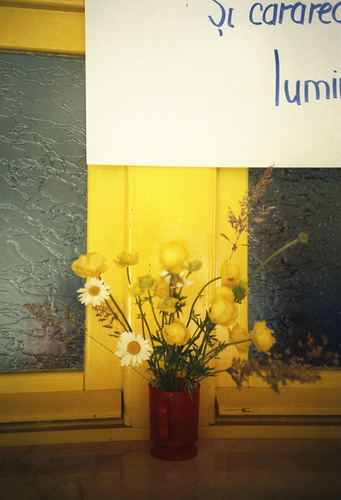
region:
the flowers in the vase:
[70, 165, 335, 391]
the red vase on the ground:
[148, 375, 197, 464]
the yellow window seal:
[0, 382, 120, 426]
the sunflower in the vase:
[111, 324, 150, 364]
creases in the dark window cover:
[0, 54, 82, 358]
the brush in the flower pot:
[213, 154, 274, 249]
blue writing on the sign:
[199, 1, 335, 128]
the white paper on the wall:
[79, 0, 336, 168]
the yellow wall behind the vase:
[83, 162, 246, 229]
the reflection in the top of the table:
[10, 443, 137, 499]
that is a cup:
[144, 383, 199, 450]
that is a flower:
[116, 329, 160, 390]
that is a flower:
[160, 320, 193, 361]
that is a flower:
[247, 318, 278, 365]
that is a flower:
[221, 323, 250, 348]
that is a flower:
[154, 237, 188, 274]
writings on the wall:
[266, 49, 337, 106]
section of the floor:
[204, 455, 226, 491]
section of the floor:
[63, 462, 116, 487]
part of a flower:
[254, 312, 279, 355]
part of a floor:
[262, 434, 279, 449]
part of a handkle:
[158, 405, 199, 487]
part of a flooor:
[226, 462, 254, 493]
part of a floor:
[245, 439, 263, 468]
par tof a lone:
[263, 424, 281, 444]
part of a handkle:
[158, 410, 173, 429]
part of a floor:
[253, 434, 270, 457]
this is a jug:
[146, 382, 206, 484]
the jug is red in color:
[173, 401, 192, 425]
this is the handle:
[157, 396, 176, 443]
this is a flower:
[210, 284, 240, 327]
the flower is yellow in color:
[165, 325, 187, 343]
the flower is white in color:
[116, 330, 139, 355]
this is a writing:
[212, 7, 325, 122]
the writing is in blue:
[271, 47, 340, 131]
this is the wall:
[16, 105, 78, 320]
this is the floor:
[227, 465, 293, 494]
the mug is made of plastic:
[137, 384, 208, 459]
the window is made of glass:
[6, 208, 69, 335]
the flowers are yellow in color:
[130, 256, 244, 341]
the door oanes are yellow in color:
[74, 294, 122, 391]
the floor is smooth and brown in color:
[232, 445, 311, 499]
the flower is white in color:
[112, 341, 162, 363]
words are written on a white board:
[204, 1, 339, 124]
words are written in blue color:
[266, 53, 337, 112]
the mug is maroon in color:
[154, 388, 204, 463]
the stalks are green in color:
[154, 354, 201, 385]